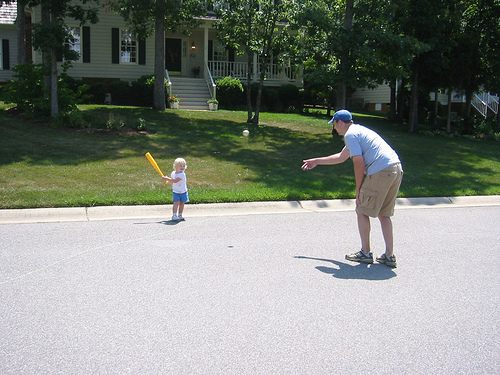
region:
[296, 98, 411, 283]
man standing on the street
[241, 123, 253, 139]
small white ball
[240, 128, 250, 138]
ball in the air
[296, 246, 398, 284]
the man's shadow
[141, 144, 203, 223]
little kid holding a yellow bat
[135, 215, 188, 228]
shadow from the little kid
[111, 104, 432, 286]
a kid and an adult playing in the street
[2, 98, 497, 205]
green grass on the ground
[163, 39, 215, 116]
steps leading up to the door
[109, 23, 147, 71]
shutters on the window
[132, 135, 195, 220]
little girl with a plastic yellow bat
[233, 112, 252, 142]
ball in the air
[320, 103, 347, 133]
man is wearing a hat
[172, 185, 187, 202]
little girl has on blue shorts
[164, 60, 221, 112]
steps up to the house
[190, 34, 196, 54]
porch light is on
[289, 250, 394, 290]
shadow of the man on the ground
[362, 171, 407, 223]
man is wearing shorts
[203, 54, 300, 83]
white railing around the porch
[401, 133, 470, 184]
green grass in the yard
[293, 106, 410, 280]
a man in the street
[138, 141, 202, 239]
a girl in the street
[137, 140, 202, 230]
a girl with a bat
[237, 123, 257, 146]
a ball in motion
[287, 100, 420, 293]
a man wearing a hat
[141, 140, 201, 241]
a girl swinging a bat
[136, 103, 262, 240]
a girl swinging at a ball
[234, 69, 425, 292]
a man throwing a ball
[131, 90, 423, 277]
a man and girl in the street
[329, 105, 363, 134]
man has blue cap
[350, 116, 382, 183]
man has blue shirt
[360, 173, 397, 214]
man has tan pants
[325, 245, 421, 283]
black and tan shoes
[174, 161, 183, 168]
girl has blonde hair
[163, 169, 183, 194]
girl has white shirt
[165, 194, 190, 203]
girl has blue shorts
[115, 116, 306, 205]
green lawn behind girl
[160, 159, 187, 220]
this is a child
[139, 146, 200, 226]
this child is learning to play baaseball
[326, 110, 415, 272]
this is a man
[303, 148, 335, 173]
the hand of a man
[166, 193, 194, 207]
the child is wearing blue shorts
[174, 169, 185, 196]
the child is wearing a white t shirt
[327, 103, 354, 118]
this is a cap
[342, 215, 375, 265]
this is a leg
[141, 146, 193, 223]
human swings yellow bat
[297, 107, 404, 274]
human throws whiteball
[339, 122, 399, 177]
shirt worn by human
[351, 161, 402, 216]
beige shorts worn by human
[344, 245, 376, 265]
shoes worn by human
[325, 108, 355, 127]
blue ball cap on a man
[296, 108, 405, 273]
man in the street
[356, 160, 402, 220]
khaki shorts of a man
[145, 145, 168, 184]
yellow plastic baseball bat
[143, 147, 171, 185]
bat in a child's hand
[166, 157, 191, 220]
child holding a baseball bat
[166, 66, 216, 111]
steps in front of a house